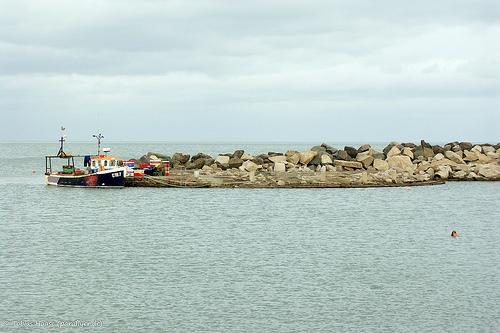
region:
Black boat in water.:
[46, 168, 119, 200]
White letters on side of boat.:
[106, 168, 129, 188]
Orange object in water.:
[446, 218, 460, 245]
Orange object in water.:
[21, 164, 43, 180]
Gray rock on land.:
[215, 150, 229, 170]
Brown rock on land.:
[186, 153, 215, 180]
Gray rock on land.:
[333, 155, 363, 172]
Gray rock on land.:
[390, 153, 415, 178]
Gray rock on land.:
[448, 147, 465, 170]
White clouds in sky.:
[135, 85, 333, 104]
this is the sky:
[233, 44, 326, 80]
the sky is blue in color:
[246, 4, 418, 85]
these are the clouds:
[186, 31, 268, 73]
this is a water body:
[206, 209, 310, 303]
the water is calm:
[283, 232, 365, 288]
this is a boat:
[56, 134, 164, 206]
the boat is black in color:
[106, 170, 122, 177]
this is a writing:
[8, 313, 73, 330]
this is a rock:
[270, 145, 287, 172]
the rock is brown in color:
[354, 149, 396, 169]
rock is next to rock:
[166, 153, 189, 166]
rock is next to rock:
[185, 157, 205, 171]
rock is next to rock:
[214, 154, 229, 164]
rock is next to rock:
[227, 150, 242, 166]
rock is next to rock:
[282, 149, 300, 166]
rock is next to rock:
[297, 149, 317, 167]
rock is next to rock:
[317, 141, 338, 154]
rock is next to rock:
[370, 153, 388, 171]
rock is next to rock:
[385, 155, 413, 166]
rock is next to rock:
[444, 150, 462, 163]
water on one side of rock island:
[10, 195, 472, 312]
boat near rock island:
[36, 145, 133, 188]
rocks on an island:
[181, 141, 478, 178]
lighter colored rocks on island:
[383, 165, 430, 179]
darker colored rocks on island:
[416, 139, 441, 156]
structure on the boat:
[83, 136, 113, 157]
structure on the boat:
[54, 120, 76, 165]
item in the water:
[15, 166, 43, 178]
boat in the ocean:
[32, 129, 156, 204]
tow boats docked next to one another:
[27, 122, 156, 204]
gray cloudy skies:
[59, 13, 407, 128]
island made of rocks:
[162, 147, 462, 194]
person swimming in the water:
[440, 223, 472, 246]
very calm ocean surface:
[79, 218, 339, 327]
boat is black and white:
[89, 134, 134, 201]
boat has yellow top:
[87, 148, 119, 169]